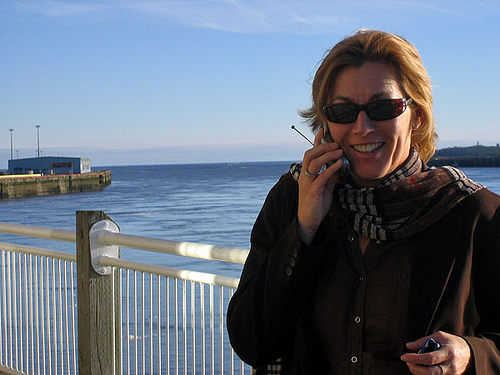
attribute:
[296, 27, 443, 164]
hair — short, shoulder length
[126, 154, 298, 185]
water — dark blue, ocean 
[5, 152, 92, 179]
building — long, gray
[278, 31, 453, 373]
woman — smiling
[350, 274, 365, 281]
button — white 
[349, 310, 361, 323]
button — white 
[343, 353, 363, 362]
button — white 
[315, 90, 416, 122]
sunglasses — dark black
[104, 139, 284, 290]
water — large, blue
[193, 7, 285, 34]
cloud — white , wispy , thin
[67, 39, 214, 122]
blue sky — blue 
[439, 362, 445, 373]
ring — silver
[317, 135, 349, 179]
cellphone — flip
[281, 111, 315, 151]
antenna — small 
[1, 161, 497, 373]
water — calm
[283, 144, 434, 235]
scarf — black, gray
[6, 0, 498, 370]
picture — day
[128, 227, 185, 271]
pole — long, white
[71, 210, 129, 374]
pole — tall, gray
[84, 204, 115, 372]
pole — short, wooden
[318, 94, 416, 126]
glasses — dark 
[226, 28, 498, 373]
woman — smiling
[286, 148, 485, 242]
scarf — plaid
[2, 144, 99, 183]
building — white 